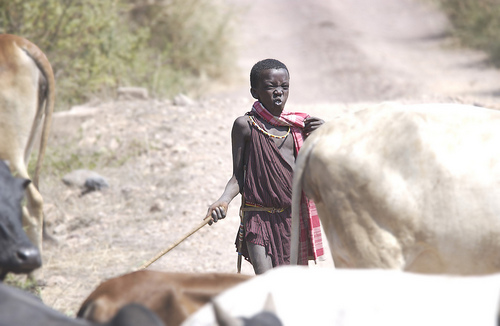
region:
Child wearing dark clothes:
[212, 46, 313, 267]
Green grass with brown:
[68, 16, 149, 93]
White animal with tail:
[285, 120, 495, 270]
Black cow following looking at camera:
[1, 140, 57, 283]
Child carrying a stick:
[142, 51, 312, 271]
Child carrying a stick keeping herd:
[146, 52, 330, 280]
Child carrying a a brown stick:
[145, 52, 341, 308]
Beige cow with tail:
[0, 22, 67, 222]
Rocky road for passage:
[290, 11, 472, 83]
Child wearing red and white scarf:
[141, 48, 324, 288]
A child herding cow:
[138, 53, 332, 292]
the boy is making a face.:
[248, 59, 291, 116]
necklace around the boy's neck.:
[248, 109, 295, 139]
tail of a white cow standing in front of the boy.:
[288, 138, 313, 266]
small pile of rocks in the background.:
[61, 167, 145, 202]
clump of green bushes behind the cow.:
[6, 0, 115, 99]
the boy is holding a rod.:
[137, 205, 214, 272]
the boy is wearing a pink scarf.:
[253, 103, 322, 260]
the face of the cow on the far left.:
[1, 175, 41, 277]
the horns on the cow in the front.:
[209, 300, 280, 325]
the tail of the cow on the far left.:
[20, 35, 53, 190]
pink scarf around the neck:
[241, 105, 328, 271]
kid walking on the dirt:
[200, 55, 336, 277]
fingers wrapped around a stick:
[128, 198, 231, 273]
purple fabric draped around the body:
[231, 116, 321, 264]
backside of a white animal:
[274, 107, 413, 284]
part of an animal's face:
[1, 163, 51, 283]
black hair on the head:
[246, 55, 289, 83]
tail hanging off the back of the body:
[275, 146, 317, 267]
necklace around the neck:
[243, 115, 296, 148]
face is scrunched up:
[258, 70, 291, 111]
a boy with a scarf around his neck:
[200, 60, 321, 276]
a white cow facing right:
[288, 98, 498, 275]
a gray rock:
[59, 168, 106, 188]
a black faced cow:
[3, 168, 41, 280]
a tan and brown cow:
[0, 30, 57, 258]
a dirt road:
[212, 1, 499, 113]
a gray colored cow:
[1, 280, 163, 325]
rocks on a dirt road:
[2, 83, 220, 315]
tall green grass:
[0, 0, 222, 107]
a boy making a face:
[203, 56, 320, 274]